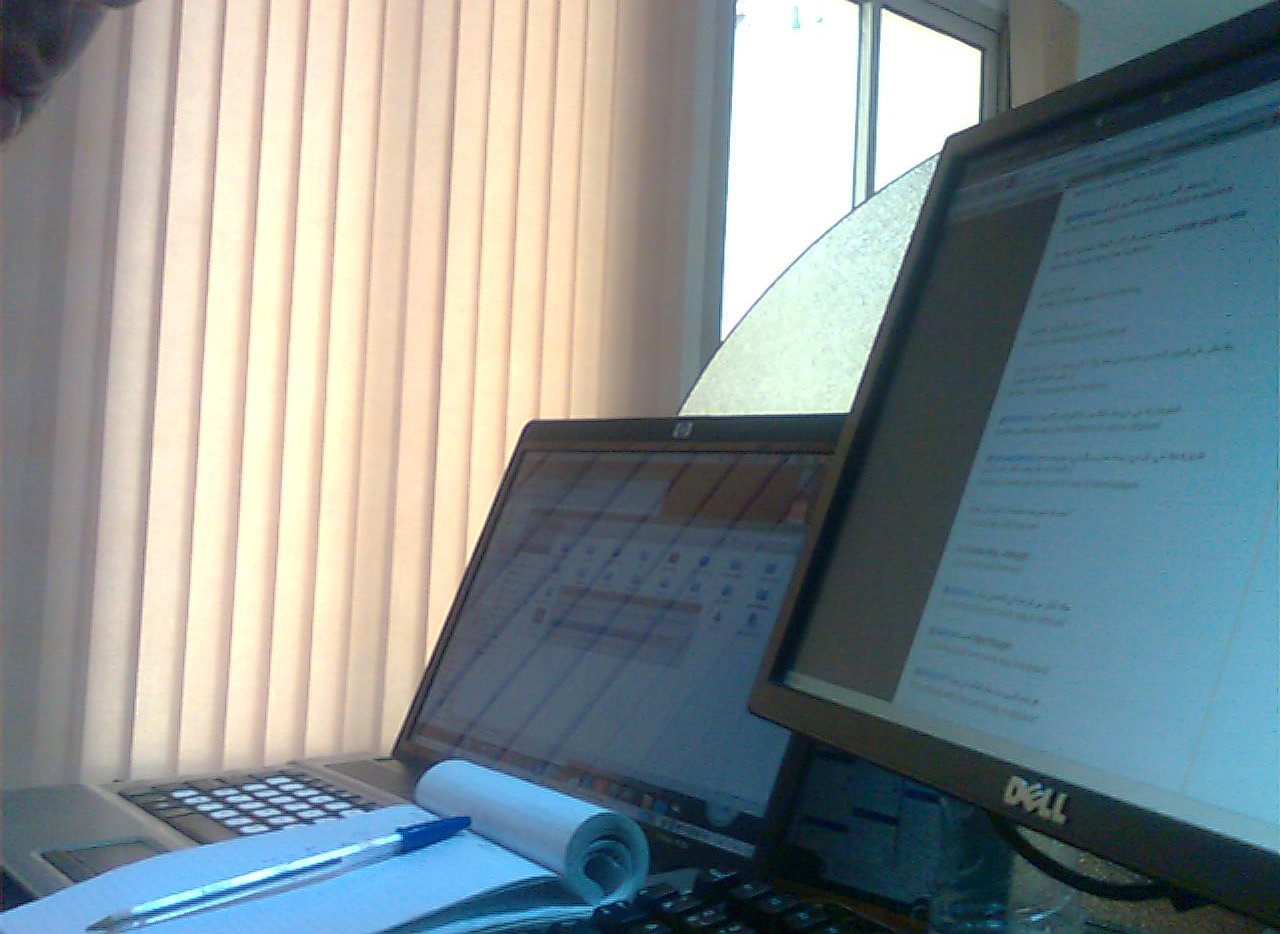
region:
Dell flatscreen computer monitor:
[741, 2, 1278, 910]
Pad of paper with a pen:
[2, 752, 652, 929]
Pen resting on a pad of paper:
[90, 821, 466, 930]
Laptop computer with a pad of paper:
[0, 410, 842, 931]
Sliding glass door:
[741, 0, 1004, 336]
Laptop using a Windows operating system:
[2, 413, 857, 930]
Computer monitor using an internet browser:
[756, 4, 1278, 931]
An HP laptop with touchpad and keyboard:
[13, 413, 845, 930]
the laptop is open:
[1, 412, 851, 931]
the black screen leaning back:
[751, 2, 1279, 925]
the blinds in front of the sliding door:
[3, 1, 736, 792]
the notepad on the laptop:
[1, 759, 653, 930]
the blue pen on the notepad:
[83, 816, 481, 931]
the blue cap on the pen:
[400, 811, 480, 858]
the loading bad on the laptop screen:
[541, 582, 711, 675]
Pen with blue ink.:
[70, 808, 461, 928]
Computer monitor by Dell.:
[814, 40, 1272, 925]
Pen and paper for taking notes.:
[1, 744, 619, 926]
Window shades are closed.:
[3, 7, 471, 753]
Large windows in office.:
[734, 5, 973, 215]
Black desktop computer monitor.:
[835, 65, 1270, 911]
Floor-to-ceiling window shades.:
[92, 3, 412, 745]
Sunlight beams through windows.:
[739, 5, 973, 187]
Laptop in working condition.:
[8, 414, 808, 913]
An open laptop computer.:
[3, 417, 860, 929]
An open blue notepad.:
[8, 755, 653, 930]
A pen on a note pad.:
[90, 810, 486, 928]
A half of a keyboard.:
[109, 761, 372, 854]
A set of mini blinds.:
[3, 0, 734, 799]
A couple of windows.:
[719, 0, 980, 356]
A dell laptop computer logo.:
[661, 404, 701, 438]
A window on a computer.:
[878, 121, 1274, 856]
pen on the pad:
[64, 803, 479, 921]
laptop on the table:
[21, 390, 840, 925]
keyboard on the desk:
[481, 849, 850, 931]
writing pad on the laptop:
[19, 746, 642, 925]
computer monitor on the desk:
[692, 6, 1275, 923]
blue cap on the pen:
[394, 803, 470, 850]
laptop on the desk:
[2, 384, 859, 905]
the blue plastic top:
[398, 804, 474, 851]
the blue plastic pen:
[82, 810, 476, 928]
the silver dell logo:
[996, 768, 1074, 826]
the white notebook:
[5, 751, 650, 930]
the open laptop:
[7, 410, 840, 931]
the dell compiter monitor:
[747, 16, 1277, 891]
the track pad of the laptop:
[42, 825, 160, 885]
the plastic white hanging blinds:
[3, 7, 761, 769]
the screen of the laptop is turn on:
[390, 396, 858, 883]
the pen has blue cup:
[71, 801, 502, 930]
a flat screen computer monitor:
[738, 0, 1275, 928]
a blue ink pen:
[80, 813, 473, 930]